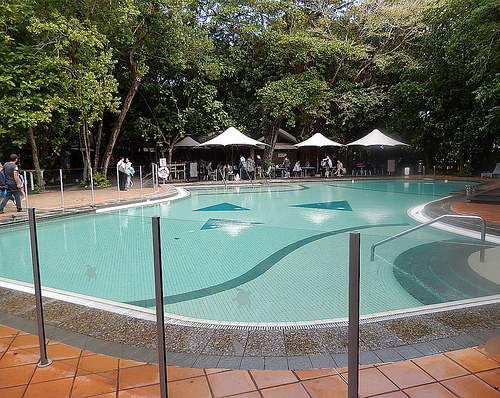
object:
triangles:
[200, 218, 265, 230]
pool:
[0, 177, 500, 328]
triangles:
[192, 202, 250, 212]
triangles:
[289, 200, 353, 211]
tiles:
[1, 343, 81, 398]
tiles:
[454, 200, 500, 222]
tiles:
[476, 184, 489, 189]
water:
[1, 183, 496, 322]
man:
[2, 154, 27, 214]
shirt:
[4, 162, 19, 185]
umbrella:
[199, 126, 271, 176]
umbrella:
[174, 132, 209, 181]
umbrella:
[294, 133, 346, 177]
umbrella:
[349, 129, 410, 176]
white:
[225, 133, 242, 141]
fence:
[0, 209, 500, 397]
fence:
[6, 164, 160, 205]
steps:
[398, 230, 499, 302]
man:
[117, 157, 129, 191]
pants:
[119, 173, 127, 190]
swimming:
[186, 195, 363, 286]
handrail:
[369, 214, 485, 264]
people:
[334, 160, 344, 177]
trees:
[0, 18, 126, 191]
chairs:
[294, 170, 303, 177]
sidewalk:
[1, 172, 164, 222]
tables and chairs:
[302, 167, 316, 178]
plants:
[81, 172, 112, 188]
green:
[20, 42, 53, 85]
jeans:
[0, 187, 22, 214]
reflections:
[217, 220, 254, 238]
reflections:
[305, 207, 337, 225]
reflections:
[356, 208, 389, 226]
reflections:
[159, 201, 172, 216]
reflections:
[404, 183, 409, 189]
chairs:
[338, 168, 347, 176]